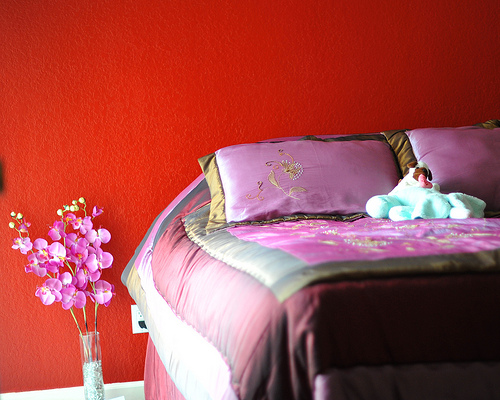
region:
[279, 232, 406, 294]
a comforter on the bed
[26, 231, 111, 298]
purple flowers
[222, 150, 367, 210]
a purple pillow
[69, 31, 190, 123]
the wall is red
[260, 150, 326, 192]
a design on the pillow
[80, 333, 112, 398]
a small vase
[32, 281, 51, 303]
Small purple flower pedal on a flower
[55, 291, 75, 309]
Small purple flower pedal on a flower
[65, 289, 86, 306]
Small purple flower pedal on a flower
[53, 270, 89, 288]
Small purple flower pedal on a flower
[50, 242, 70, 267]
Small purple flower pedal on a flower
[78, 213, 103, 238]
Small purple flower pedal on a flower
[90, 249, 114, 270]
Small purple flower pedal on a flower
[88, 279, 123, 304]
Small purple flower pedal on a flower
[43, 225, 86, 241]
Small purple flower pedal on a flower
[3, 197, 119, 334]
pink flowers next to bed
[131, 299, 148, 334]
electrical outlet behind a bed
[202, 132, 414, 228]
pink pillow on a bed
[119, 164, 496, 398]
pink blanket on a bed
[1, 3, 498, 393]
wall painted the color red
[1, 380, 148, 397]
white wainscoting between the floor and wall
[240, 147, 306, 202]
gold and white decoration on pillow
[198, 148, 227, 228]
gold border around pillow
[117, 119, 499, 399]
made bed in room with red colored walls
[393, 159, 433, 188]
Small dog plush toy on bed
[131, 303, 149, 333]
White outlet behind the bed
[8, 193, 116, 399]
Flower vase in front of the red wall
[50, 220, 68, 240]
Purple flower inside of the vase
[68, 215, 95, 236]
Purple flower inside of the vase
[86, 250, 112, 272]
Purple flower inside of the vase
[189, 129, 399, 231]
Pillow laying on the bed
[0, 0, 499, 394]
Red wall behind the bed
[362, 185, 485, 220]
Blue plush toy on the bed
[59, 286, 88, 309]
Purple flower inside of the vase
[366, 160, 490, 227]
a bear on the bed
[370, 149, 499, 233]
a bear on the bed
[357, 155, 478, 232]
a bear on the bed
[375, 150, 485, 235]
a bear on the bed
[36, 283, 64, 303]
a purple flower in vase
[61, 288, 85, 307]
a purple flower in vase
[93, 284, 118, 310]
a purple flower in vase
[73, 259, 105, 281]
a purple flower in vase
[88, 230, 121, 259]
a purple flower in vase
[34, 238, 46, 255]
a purple flower in vase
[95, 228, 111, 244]
purple petal on flower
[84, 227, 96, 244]
purple petal on flower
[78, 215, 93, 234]
purple petal on flower